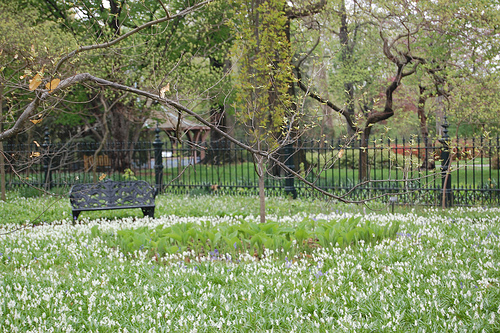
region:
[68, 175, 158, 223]
green metal bench on lawn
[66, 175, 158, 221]
metal bench on the yard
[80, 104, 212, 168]
wooden gazebo behind the fence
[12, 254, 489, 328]
white flower in the grass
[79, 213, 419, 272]
green grass in the middle of white flowers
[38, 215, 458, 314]
white flowers surrounding a patch of green grass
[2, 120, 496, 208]
metal fence around the property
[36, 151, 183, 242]
green bench in the park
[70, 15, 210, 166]
wooden gazebo behind the metal fence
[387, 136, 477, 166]
red plants behind the fence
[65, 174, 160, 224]
The black park bench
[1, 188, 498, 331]
The grass with wildflowers in it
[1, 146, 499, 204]
The grass with no wildflowers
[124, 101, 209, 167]
The gazebo in the background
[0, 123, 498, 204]
The black metal fence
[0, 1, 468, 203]
The bare branch above the bench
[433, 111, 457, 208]
The fence post furthest right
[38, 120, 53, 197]
The fence post furthest left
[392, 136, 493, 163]
The red bushes in the background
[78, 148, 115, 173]
The gold object near the gazebo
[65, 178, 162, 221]
green metal bench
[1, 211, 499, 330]
white flowers in green grass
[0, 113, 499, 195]
long metal fence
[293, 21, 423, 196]
brown bare tree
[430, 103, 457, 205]
metal fence post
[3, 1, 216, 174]
tall green tree with brown trunk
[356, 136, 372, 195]
brown tree trunk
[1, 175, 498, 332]
metal bench sitting before green grass with white flowers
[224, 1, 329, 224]
tree with bare branches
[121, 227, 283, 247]
patch of plain green grass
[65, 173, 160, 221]
The black, metal bench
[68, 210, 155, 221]
The legs of the bench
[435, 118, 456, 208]
The pole furthest to the right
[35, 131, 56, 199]
The pole furthest to the left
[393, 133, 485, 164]
The red bushes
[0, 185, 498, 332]
The field with wildflowers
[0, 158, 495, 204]
The field of grass with no wildflowers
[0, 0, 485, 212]
The bare tree branch over the bench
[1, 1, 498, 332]
an outdoor scene of a park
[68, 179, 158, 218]
an iron park bench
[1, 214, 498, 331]
wild flowers growing in the tall grass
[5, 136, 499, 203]
an iron fence along the park boarder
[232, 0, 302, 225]
a tree in the middle of the park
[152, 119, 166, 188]
iron fence posts along the fence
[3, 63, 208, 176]
a building behind the park surrounded by trees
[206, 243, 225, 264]
purple wild flowers growing in the grass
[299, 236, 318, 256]
red wild flowers growing in the grass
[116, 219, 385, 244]
a green area without wild flowers